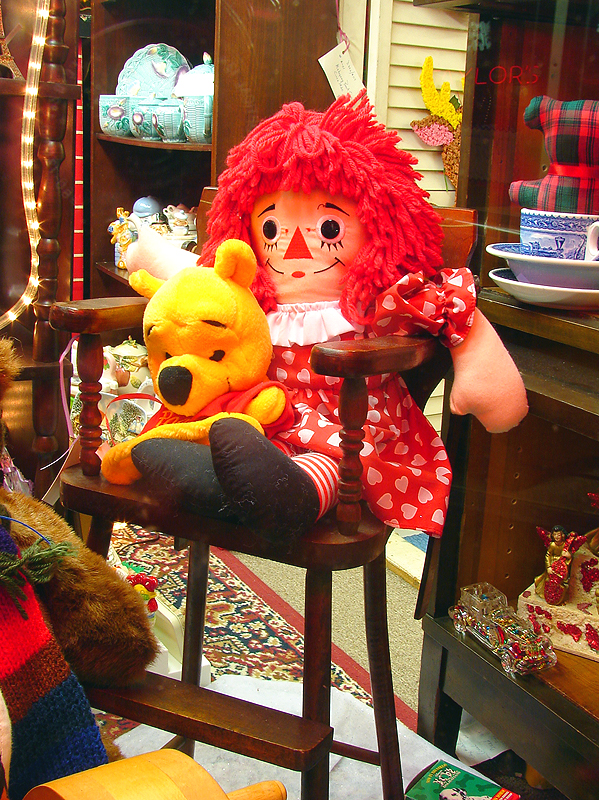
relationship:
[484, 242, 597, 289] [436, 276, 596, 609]
bowl on a table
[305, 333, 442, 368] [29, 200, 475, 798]
arm on a chair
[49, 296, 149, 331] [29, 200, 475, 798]
arm on a chair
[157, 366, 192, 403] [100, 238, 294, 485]
nose on stuffed animal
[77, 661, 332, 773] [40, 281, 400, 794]
foot rest on a chair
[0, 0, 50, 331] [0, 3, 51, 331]
lights of lights